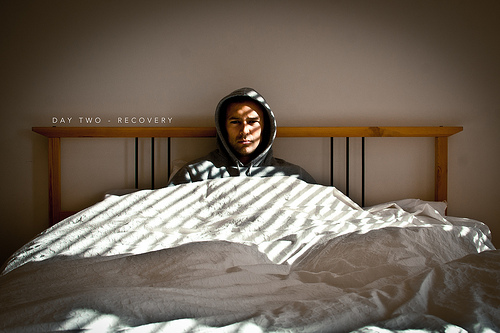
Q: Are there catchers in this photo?
A: No, there are no catchers.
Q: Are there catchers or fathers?
A: No, there are no catchers or fathers.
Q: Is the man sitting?
A: Yes, the man is sitting.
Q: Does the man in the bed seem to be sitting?
A: Yes, the man is sitting.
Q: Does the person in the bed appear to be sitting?
A: Yes, the man is sitting.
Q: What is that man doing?
A: The man is sitting.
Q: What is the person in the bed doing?
A: The man is sitting.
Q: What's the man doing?
A: The man is sitting.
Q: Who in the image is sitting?
A: The man is sitting.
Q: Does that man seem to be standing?
A: No, the man is sitting.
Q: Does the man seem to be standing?
A: No, the man is sitting.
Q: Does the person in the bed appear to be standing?
A: No, the man is sitting.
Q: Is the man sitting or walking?
A: The man is sitting.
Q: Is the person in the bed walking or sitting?
A: The man is sitting.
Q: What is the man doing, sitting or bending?
A: The man is sitting.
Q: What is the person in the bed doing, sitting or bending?
A: The man is sitting.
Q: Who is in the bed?
A: The man is in the bed.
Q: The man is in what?
A: The man is in the bed.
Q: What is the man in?
A: The man is in the bed.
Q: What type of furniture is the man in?
A: The man is in the bed.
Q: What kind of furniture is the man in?
A: The man is in the bed.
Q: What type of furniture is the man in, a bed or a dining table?
A: The man is in a bed.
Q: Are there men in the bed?
A: Yes, there is a man in the bed.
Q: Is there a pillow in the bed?
A: No, there is a man in the bed.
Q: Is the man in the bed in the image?
A: Yes, the man is in the bed.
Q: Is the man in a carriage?
A: No, the man is in the bed.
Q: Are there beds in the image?
A: Yes, there is a bed.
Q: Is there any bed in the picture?
A: Yes, there is a bed.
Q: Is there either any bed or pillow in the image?
A: Yes, there is a bed.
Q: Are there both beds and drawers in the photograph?
A: No, there is a bed but no drawers.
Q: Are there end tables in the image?
A: No, there are no end tables.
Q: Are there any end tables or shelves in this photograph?
A: No, there are no end tables or shelves.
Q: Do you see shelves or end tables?
A: No, there are no end tables or shelves.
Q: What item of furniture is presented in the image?
A: The piece of furniture is a bed.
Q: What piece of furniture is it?
A: The piece of furniture is a bed.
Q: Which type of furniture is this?
A: This is a bed.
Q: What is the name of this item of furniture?
A: This is a bed.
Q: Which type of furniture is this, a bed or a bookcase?
A: This is a bed.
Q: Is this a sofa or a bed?
A: This is a bed.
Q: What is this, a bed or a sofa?
A: This is a bed.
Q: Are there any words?
A: Yes, there are words.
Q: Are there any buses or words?
A: Yes, there are words.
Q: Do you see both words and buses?
A: No, there are words but no buses.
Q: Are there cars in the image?
A: No, there are no cars.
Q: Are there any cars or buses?
A: No, there are no cars or buses.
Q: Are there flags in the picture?
A: No, there are no flags.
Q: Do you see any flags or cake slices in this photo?
A: No, there are no flags or cake slices.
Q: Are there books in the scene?
A: No, there are no books.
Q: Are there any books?
A: No, there are no books.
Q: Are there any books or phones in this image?
A: No, there are no books or phones.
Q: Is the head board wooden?
A: Yes, the head board is wooden.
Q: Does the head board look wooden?
A: Yes, the head board is wooden.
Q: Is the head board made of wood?
A: Yes, the head board is made of wood.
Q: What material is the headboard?
A: The headboard is made of wood.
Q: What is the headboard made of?
A: The headboard is made of wood.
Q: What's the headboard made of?
A: The headboard is made of wood.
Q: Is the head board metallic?
A: No, the head board is wooden.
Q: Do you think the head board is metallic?
A: No, the head board is wooden.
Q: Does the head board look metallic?
A: No, the head board is wooden.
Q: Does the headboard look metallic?
A: No, the headboard is wooden.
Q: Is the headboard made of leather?
A: No, the headboard is made of wood.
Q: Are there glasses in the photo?
A: No, there are no glasses.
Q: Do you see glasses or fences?
A: No, there are no glasses or fences.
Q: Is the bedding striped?
A: Yes, the bedding is striped.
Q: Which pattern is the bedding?
A: The bedding is striped.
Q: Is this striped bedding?
A: Yes, this is striped bedding.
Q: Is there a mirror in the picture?
A: No, there are no mirrors.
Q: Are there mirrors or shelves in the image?
A: No, there are no mirrors or shelves.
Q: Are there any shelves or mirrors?
A: No, there are no mirrors or shelves.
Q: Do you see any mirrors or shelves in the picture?
A: No, there are no mirrors or shelves.